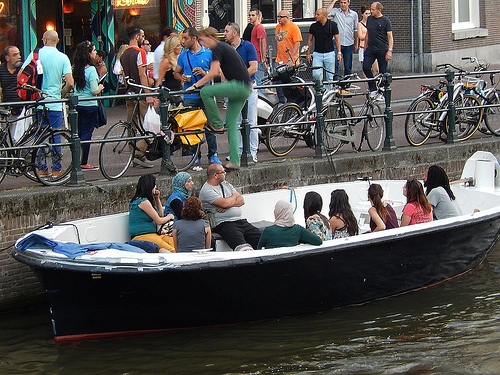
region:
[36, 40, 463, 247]
group of people outdoors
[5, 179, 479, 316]
people sitting in a boat waiting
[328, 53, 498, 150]
bicycles on the walkway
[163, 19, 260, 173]
person climbing into or out of the boat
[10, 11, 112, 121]
man and woman in turquoise t shirts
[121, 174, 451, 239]
people in the boat and looking at people with bikes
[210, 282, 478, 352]
murky colored water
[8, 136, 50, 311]
brick retaining wall to water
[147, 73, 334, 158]
man with foot on railing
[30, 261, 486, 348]
small boat black outside white inside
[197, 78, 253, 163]
Green pants on a man.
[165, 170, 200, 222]
Woman sitting on bus in head gear.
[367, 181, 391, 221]
Brown pony tail coming off a females head.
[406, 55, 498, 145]
Bicycles leaning against railing.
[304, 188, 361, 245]
Two girls sitting on boat.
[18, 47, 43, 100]
Red black and white backpack on a mans shoulder.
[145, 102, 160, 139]
White plastic bag a person is carrying.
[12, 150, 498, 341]
Boat in the water with people on it.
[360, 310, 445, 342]
Ripples in the water.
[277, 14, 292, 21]
Black glasses on a bald mans head.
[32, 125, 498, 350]
10 people sitting in black boat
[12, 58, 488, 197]
bicycles leaning against metal fence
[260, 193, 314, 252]
woman wearing a head wrap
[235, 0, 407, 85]
people walking on sidewalk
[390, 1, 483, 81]
red brick building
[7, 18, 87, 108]
man with red and black backpack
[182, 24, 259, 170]
man climbing over fence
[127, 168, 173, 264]
woman wearing yellow pants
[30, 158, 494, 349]
black and white boat in the water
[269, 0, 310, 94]
man with an orange t-shirt walking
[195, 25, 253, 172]
Man climbing over railing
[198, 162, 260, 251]
man sitting with arms crossed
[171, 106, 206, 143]
plastic yellow bag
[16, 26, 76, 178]
Man carrying red and black backpack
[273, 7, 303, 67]
Man wearing orange t-shirt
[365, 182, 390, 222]
Ponytail hairstyle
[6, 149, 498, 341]
People sitting in a boat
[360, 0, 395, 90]
Man dressed all in black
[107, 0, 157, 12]
Neon sign in window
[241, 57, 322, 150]
Motor Scooter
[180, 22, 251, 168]
man climbing over railing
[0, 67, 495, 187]
long metal railing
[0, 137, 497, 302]
brick wall coming out of water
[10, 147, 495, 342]
black and white boat with passengers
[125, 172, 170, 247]
woman sitting in boat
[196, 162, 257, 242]
man sitting in boat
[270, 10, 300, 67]
man next to building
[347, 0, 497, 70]
brick building with window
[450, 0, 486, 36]
window on brick building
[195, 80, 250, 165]
bright green colored jeans